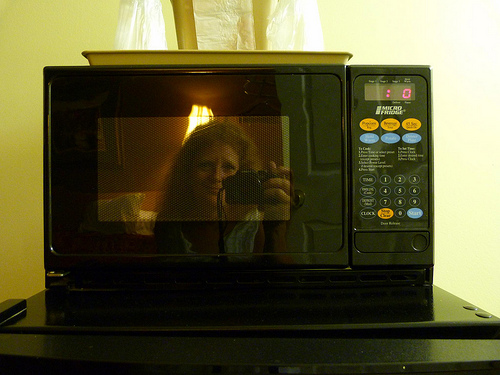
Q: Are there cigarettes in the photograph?
A: No, there are no cigarettes.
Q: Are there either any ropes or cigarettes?
A: No, there are no cigarettes or ropes.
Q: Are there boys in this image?
A: No, there are no boys.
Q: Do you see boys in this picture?
A: No, there are no boys.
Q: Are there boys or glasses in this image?
A: No, there are no boys or glasses.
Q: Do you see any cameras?
A: Yes, there is a camera.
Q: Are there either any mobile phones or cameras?
A: Yes, there is a camera.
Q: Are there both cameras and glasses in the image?
A: No, there is a camera but no glasses.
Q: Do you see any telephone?
A: No, there are no phones.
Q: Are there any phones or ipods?
A: No, there are no phones or ipods.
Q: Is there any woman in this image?
A: Yes, there is a woman.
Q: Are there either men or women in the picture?
A: Yes, there is a woman.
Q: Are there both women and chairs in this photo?
A: No, there is a woman but no chairs.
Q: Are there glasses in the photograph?
A: No, there are no glasses.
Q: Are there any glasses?
A: No, there are no glasses.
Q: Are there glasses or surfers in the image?
A: No, there are no glasses or surfers.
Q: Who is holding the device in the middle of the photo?
A: The woman is holding the camera.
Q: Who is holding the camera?
A: The woman is holding the camera.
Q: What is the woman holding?
A: The woman is holding the camera.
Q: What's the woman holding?
A: The woman is holding the camera.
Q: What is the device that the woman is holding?
A: The device is a camera.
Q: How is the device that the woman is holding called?
A: The device is a camera.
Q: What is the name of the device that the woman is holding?
A: The device is a camera.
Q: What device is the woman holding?
A: The woman is holding the camera.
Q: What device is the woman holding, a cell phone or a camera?
A: The woman is holding a camera.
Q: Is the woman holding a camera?
A: Yes, the woman is holding a camera.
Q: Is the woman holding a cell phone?
A: No, the woman is holding a camera.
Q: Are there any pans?
A: Yes, there is a pan.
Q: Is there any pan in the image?
A: Yes, there is a pan.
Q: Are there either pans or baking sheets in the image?
A: Yes, there is a pan.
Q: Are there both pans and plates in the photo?
A: No, there is a pan but no plates.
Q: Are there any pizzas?
A: No, there are no pizzas.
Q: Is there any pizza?
A: No, there are no pizzas.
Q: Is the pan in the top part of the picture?
A: Yes, the pan is in the top of the image.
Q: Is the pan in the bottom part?
A: No, the pan is in the top of the image.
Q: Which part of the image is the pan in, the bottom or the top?
A: The pan is in the top of the image.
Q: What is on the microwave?
A: The pan is on the microwave.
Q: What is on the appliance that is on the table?
A: The pan is on the microwave.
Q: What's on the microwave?
A: The pan is on the microwave.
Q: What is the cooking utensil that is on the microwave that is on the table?
A: The cooking utensil is a pan.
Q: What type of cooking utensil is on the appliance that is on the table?
A: The cooking utensil is a pan.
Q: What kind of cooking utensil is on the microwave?
A: The cooking utensil is a pan.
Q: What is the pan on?
A: The pan is on the microwave.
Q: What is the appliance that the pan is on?
A: The appliance is a microwave.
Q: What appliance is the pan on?
A: The pan is on the microwave.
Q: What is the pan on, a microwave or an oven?
A: The pan is on a microwave.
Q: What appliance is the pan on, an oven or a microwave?
A: The pan is on a microwave.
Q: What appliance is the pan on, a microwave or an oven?
A: The pan is on a microwave.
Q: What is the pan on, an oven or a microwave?
A: The pan is on a microwave.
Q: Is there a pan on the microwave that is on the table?
A: Yes, there is a pan on the microwave.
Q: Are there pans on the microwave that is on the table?
A: Yes, there is a pan on the microwave.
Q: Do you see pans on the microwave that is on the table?
A: Yes, there is a pan on the microwave.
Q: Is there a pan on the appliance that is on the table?
A: Yes, there is a pan on the microwave.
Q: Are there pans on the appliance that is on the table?
A: Yes, there is a pan on the microwave.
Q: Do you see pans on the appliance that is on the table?
A: Yes, there is a pan on the microwave.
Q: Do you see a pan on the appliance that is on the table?
A: Yes, there is a pan on the microwave.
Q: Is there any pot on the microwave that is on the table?
A: No, there is a pan on the microwave.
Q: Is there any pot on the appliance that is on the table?
A: No, there is a pan on the microwave.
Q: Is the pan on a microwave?
A: Yes, the pan is on a microwave.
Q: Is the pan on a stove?
A: No, the pan is on a microwave.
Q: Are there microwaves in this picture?
A: Yes, there is a microwave.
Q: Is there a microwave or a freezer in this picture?
A: Yes, there is a microwave.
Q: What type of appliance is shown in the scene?
A: The appliance is a microwave.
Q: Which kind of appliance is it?
A: The appliance is a microwave.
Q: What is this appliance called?
A: This is a microwave.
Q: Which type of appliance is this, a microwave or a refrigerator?
A: This is a microwave.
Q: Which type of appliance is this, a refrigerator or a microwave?
A: This is a microwave.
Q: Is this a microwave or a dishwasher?
A: This is a microwave.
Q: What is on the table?
A: The microwave is on the table.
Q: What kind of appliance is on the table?
A: The appliance is a microwave.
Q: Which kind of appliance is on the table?
A: The appliance is a microwave.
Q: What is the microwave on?
A: The microwave is on the table.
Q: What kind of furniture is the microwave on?
A: The microwave is on the table.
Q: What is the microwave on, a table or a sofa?
A: The microwave is on a table.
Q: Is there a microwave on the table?
A: Yes, there is a microwave on the table.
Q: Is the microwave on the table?
A: Yes, the microwave is on the table.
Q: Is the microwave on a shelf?
A: No, the microwave is on the table.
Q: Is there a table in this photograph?
A: Yes, there is a table.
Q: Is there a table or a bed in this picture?
A: Yes, there is a table.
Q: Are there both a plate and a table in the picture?
A: No, there is a table but no plates.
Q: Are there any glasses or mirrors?
A: No, there are no glasses or mirrors.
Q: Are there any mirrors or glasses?
A: No, there are no glasses or mirrors.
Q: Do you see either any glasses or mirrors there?
A: No, there are no glasses or mirrors.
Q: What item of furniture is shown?
A: The piece of furniture is a table.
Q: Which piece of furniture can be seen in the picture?
A: The piece of furniture is a table.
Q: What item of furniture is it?
A: The piece of furniture is a table.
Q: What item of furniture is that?
A: This is a table.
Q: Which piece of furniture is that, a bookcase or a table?
A: This is a table.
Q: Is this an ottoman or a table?
A: This is a table.